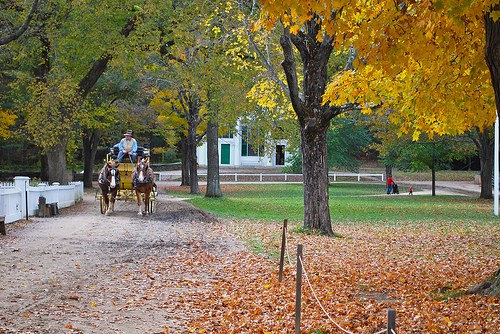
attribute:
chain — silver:
[288, 283, 338, 327]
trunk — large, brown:
[282, 26, 346, 239]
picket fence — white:
[1, 175, 85, 226]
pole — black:
[292, 237, 308, 324]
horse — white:
[130, 161, 155, 216]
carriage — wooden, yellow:
[99, 149, 157, 214]